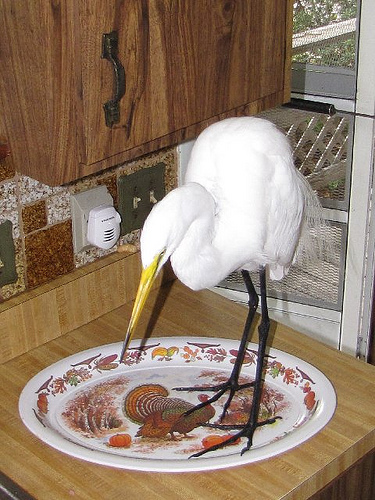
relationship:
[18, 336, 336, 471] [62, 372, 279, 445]
plate has pattern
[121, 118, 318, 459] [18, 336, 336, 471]
crane standing on plate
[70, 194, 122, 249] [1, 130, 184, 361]
plug in wall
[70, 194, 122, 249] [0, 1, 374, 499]
plug in room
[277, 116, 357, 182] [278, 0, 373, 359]
lattice on patio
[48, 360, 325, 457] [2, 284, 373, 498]
treats on countertop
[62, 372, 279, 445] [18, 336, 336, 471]
pattern on plate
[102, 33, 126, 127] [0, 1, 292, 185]
handle on cabinet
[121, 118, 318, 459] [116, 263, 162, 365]
crane has beak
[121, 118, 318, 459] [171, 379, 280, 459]
crane has feet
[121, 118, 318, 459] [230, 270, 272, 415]
crane has legs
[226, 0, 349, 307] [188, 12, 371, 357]
screen on door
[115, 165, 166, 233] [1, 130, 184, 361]
light panel on wall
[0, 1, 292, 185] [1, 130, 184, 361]
cabinet on wall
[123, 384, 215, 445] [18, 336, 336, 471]
turkey on plate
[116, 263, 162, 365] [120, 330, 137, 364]
beak has tip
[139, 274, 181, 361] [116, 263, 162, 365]
shadow of beak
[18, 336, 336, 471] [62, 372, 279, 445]
plate with pattern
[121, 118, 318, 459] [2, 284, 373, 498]
crane on countertop